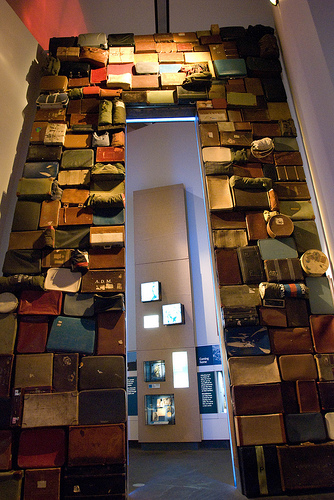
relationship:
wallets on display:
[217, 173, 299, 313] [26, 31, 293, 363]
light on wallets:
[94, 9, 206, 44] [97, 36, 231, 89]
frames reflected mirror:
[127, 172, 221, 495] [133, 340, 210, 426]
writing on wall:
[5, 459, 261, 497] [20, 60, 318, 321]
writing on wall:
[202, 278, 288, 441] [128, 128, 192, 173]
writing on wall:
[158, 248, 253, 419] [210, 353, 240, 425]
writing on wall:
[208, 323, 257, 454] [156, 122, 190, 173]